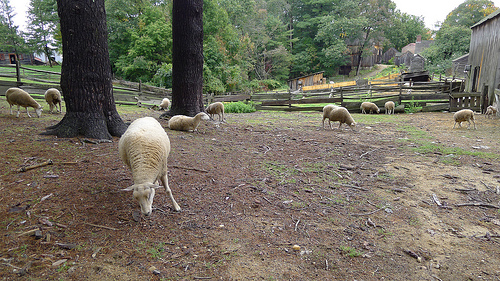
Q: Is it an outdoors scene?
A: Yes, it is outdoors.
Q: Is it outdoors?
A: Yes, it is outdoors.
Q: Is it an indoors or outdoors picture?
A: It is outdoors.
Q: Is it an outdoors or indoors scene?
A: It is outdoors.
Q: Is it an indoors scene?
A: No, it is outdoors.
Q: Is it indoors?
A: No, it is outdoors.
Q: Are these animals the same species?
A: Yes, all the animals are sheep.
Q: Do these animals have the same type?
A: Yes, all the animals are sheep.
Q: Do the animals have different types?
A: No, all the animals are sheep.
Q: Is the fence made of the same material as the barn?
A: Yes, both the fence and the barn are made of wood.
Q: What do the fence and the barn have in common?
A: The material, both the fence and the barn are wooden.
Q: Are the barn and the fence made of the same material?
A: Yes, both the barn and the fence are made of wood.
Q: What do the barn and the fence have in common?
A: The material, both the barn and the fence are wooden.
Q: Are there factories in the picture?
A: No, there are no factories.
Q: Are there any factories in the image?
A: No, there are no factories.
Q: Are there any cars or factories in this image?
A: No, there are no factories or cars.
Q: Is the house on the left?
A: Yes, the house is on the left of the image.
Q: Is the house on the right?
A: No, the house is on the left of the image.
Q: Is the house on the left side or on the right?
A: The house is on the left of the image.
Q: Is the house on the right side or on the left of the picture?
A: The house is on the left of the image.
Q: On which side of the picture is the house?
A: The house is on the left of the image.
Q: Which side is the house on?
A: The house is on the left of the image.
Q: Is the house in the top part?
A: Yes, the house is in the top of the image.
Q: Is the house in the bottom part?
A: No, the house is in the top of the image.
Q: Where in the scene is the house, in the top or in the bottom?
A: The house is in the top of the image.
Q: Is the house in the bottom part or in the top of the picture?
A: The house is in the top of the image.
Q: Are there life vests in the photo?
A: No, there are no life vests.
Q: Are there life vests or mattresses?
A: No, there are no life vests or mattresses.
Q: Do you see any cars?
A: No, there are no cars.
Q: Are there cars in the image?
A: No, there are no cars.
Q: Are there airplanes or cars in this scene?
A: No, there are no cars or airplanes.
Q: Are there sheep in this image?
A: Yes, there is a sheep.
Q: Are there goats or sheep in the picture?
A: Yes, there is a sheep.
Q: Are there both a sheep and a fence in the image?
A: Yes, there are both a sheep and a fence.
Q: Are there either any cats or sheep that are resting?
A: Yes, the sheep is resting.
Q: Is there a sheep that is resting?
A: Yes, there is a sheep that is resting.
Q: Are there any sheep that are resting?
A: Yes, there is a sheep that is resting.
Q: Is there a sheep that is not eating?
A: Yes, there is a sheep that is resting.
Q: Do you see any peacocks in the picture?
A: No, there are no peacocks.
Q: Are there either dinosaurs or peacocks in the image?
A: No, there are no peacocks or dinosaurs.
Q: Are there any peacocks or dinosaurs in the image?
A: No, there are no peacocks or dinosaurs.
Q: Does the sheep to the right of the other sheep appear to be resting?
A: Yes, the sheep is resting.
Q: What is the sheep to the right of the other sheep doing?
A: The sheep is resting.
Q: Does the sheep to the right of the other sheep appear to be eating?
A: No, the sheep is resting.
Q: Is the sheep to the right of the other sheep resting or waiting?
A: The sheep is resting.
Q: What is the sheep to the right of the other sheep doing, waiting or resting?
A: The sheep is resting.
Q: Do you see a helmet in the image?
A: No, there are no helmets.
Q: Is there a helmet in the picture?
A: No, there are no helmets.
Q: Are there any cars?
A: No, there are no cars.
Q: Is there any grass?
A: Yes, there is grass.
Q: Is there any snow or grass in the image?
A: Yes, there is grass.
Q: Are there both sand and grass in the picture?
A: No, there is grass but no sand.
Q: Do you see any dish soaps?
A: No, there are no dish soaps.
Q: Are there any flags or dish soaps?
A: No, there are no dish soaps or flags.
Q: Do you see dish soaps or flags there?
A: No, there are no dish soaps or flags.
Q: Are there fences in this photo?
A: Yes, there is a fence.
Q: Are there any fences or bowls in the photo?
A: Yes, there is a fence.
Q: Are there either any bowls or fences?
A: Yes, there is a fence.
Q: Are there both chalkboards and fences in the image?
A: No, there is a fence but no chalkboards.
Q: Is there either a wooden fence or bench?
A: Yes, there is a wood fence.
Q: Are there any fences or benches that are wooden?
A: Yes, the fence is wooden.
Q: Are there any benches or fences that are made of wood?
A: Yes, the fence is made of wood.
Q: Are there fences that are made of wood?
A: Yes, there is a fence that is made of wood.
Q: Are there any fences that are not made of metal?
A: Yes, there is a fence that is made of wood.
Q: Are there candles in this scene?
A: No, there are no candles.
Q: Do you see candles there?
A: No, there are no candles.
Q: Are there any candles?
A: No, there are no candles.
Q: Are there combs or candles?
A: No, there are no candles or combs.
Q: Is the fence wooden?
A: Yes, the fence is wooden.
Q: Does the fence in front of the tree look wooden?
A: Yes, the fence is wooden.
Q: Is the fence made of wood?
A: Yes, the fence is made of wood.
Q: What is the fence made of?
A: The fence is made of wood.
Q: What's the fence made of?
A: The fence is made of wood.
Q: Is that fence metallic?
A: No, the fence is wooden.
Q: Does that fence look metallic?
A: No, the fence is wooden.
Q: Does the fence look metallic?
A: No, the fence is wooden.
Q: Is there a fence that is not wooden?
A: No, there is a fence but it is wooden.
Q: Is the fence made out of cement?
A: No, the fence is made of wood.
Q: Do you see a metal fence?
A: No, there is a fence but it is made of wood.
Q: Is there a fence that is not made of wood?
A: No, there is a fence but it is made of wood.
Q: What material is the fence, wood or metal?
A: The fence is made of wood.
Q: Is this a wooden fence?
A: Yes, this is a wooden fence.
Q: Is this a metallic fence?
A: No, this is a wooden fence.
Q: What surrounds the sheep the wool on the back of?
A: The fence surrounds the sheep.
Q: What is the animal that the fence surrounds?
A: The animal is a sheep.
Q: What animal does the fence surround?
A: The fence surrounds the sheep.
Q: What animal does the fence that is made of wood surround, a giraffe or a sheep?
A: The fence surrounds a sheep.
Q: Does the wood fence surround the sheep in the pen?
A: Yes, the fence surrounds the sheep.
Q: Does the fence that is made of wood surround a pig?
A: No, the fence surrounds the sheep.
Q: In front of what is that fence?
A: The fence is in front of the tree.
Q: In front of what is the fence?
A: The fence is in front of the tree.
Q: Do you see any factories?
A: No, there are no factories.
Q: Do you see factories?
A: No, there are no factories.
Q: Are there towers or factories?
A: No, there are no factories or towers.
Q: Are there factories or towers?
A: No, there are no factories or towers.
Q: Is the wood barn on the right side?
A: Yes, the barn is on the right of the image.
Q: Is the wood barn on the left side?
A: No, the barn is on the right of the image.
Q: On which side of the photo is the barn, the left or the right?
A: The barn is on the right of the image.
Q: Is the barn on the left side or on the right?
A: The barn is on the right of the image.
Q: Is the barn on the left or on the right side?
A: The barn is on the right of the image.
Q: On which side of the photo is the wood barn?
A: The barn is on the right of the image.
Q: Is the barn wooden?
A: Yes, the barn is wooden.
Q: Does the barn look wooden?
A: Yes, the barn is wooden.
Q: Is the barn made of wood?
A: Yes, the barn is made of wood.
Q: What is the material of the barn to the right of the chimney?
A: The barn is made of wood.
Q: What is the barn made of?
A: The barn is made of wood.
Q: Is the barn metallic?
A: No, the barn is wooden.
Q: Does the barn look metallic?
A: No, the barn is wooden.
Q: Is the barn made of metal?
A: No, the barn is made of wood.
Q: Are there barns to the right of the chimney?
A: Yes, there is a barn to the right of the chimney.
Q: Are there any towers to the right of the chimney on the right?
A: No, there is a barn to the right of the chimney.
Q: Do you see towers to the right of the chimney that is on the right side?
A: No, there is a barn to the right of the chimney.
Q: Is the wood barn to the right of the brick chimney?
A: Yes, the barn is to the right of the chimney.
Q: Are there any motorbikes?
A: No, there are no motorbikes.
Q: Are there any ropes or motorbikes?
A: No, there are no motorbikes or ropes.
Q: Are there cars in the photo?
A: No, there are no cars.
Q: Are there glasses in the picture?
A: No, there are no glasses.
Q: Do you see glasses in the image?
A: No, there are no glasses.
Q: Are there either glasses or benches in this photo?
A: No, there are no glasses or benches.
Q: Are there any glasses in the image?
A: No, there are no glasses.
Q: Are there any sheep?
A: Yes, there is a sheep.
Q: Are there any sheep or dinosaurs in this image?
A: Yes, there is a sheep.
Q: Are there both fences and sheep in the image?
A: Yes, there are both a sheep and a fence.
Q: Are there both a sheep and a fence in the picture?
A: Yes, there are both a sheep and a fence.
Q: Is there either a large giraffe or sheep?
A: Yes, there is a large sheep.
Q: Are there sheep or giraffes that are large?
A: Yes, the sheep is large.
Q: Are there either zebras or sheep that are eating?
A: Yes, the sheep is eating.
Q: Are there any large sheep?
A: Yes, there is a large sheep.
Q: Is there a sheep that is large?
A: Yes, there is a sheep that is large.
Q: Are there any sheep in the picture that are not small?
A: Yes, there is a large sheep.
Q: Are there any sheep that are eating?
A: Yes, there is a sheep that is eating.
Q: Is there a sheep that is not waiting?
A: Yes, there is a sheep that is eating.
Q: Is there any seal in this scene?
A: No, there are no seals.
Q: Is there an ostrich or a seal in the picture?
A: No, there are no seals or ostriches.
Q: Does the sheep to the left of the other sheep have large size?
A: Yes, the sheep is large.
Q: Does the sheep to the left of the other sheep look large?
A: Yes, the sheep is large.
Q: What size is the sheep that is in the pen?
A: The sheep is large.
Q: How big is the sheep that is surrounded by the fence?
A: The sheep is large.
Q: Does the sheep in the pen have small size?
A: No, the sheep is large.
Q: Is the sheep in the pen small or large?
A: The sheep is large.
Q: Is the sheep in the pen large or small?
A: The sheep is large.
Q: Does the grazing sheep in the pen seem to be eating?
A: Yes, the sheep is eating.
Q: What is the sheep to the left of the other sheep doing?
A: The sheep is eating.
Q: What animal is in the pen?
A: The animal is a sheep.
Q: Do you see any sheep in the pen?
A: Yes, there is a sheep in the pen.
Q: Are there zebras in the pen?
A: No, there is a sheep in the pen.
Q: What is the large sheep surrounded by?
A: The sheep is surrounded by the fence.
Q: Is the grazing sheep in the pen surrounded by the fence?
A: Yes, the sheep is surrounded by the fence.